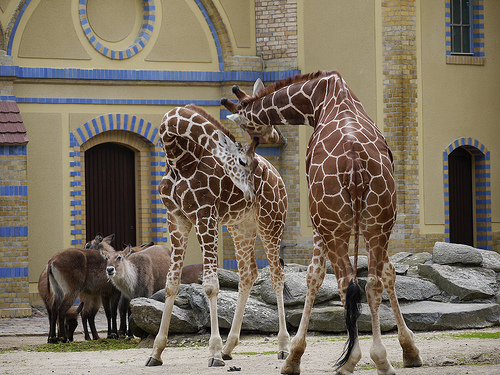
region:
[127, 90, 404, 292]
two giraffes are near each other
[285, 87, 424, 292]
brown and white spots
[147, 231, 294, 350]
giraffe has white legs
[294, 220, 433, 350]
giraffe has brown legs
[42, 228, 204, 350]
deer are behind giraffes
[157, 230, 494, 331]
grey rock pile behind giraffes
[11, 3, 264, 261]
large house in back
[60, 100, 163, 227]
blue and yellow arched door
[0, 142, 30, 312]
brick wall next to door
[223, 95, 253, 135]
giraffe has light ears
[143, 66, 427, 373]
A pair of two giraffe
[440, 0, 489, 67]
Window on a building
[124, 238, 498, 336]
Very big gray rocks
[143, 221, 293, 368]
Four legs of a giraffe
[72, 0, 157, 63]
Round architecture on a building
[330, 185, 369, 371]
Tail of a giraffe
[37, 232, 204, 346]
A bunch of gray mules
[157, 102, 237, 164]
A long neck of a giraffe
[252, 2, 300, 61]
Bricks on the building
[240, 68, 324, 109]
Mane on giraffe's neck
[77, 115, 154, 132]
blue stripes around the door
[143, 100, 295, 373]
giraffe with his head turned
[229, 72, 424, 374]
giraffe with head turned to the side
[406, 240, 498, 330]
rock formations in front of the building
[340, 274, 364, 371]
black tail of the giraffe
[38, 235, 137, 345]
two cows standing around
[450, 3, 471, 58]
window on the building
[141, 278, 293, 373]
legs of the giraffe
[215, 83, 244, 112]
horns on the giraffe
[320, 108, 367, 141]
white lines on the giraffe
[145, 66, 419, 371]
two giraffes on a zoo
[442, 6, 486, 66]
blue and yelow window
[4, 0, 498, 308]
big yellow building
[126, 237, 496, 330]
a bunch of rocks on the ground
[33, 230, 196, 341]
three deers behind rocks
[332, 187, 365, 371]
large hairy tail of giraffe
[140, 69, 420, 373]
two giraffes with head down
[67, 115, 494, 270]
two blue and yellow arched doorways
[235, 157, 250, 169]
little right eye of giraffe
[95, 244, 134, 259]
two little furry ears of deer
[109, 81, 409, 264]
two giraffes bended over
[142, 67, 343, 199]
two giraffes bended over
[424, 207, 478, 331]
the gray large rocks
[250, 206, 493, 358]
the gray large rocks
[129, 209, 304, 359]
the gray large rocks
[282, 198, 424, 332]
the gray large rocks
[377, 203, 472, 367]
the gray large rocks